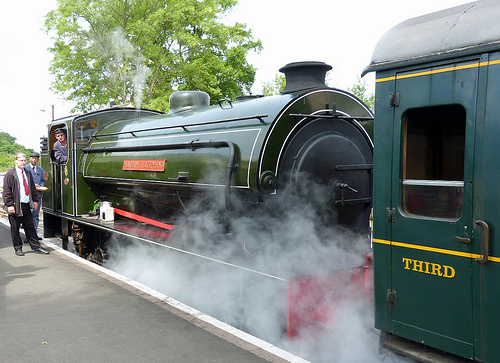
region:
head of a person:
[10, 150, 30, 165]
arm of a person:
[28, 179, 43, 200]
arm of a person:
[0, 175, 20, 207]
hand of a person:
[0, 208, 20, 214]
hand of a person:
[28, 195, 43, 213]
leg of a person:
[3, 213, 27, 248]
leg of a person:
[15, 210, 46, 242]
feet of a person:
[28, 242, 45, 253]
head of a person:
[53, 125, 73, 145]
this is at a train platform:
[18, 22, 476, 333]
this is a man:
[2, 155, 44, 250]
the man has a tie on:
[2, 145, 42, 257]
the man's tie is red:
[1, 167, 38, 197]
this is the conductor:
[42, 114, 94, 206]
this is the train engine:
[84, 89, 344, 361]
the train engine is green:
[162, 60, 387, 327]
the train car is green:
[394, 65, 498, 304]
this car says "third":
[392, 243, 482, 288]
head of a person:
[8, 146, 26, 173]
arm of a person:
[28, 173, 43, 203]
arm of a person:
[0, 173, 22, 213]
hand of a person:
[29, 197, 39, 209]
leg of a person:
[5, 202, 24, 239]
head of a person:
[23, 148, 50, 166]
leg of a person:
[22, 206, 46, 239]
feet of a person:
[3, 246, 25, 258]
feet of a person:
[29, 246, 56, 258]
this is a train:
[12, 100, 427, 350]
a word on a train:
[388, 249, 481, 299]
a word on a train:
[110, 150, 172, 174]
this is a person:
[2, 148, 50, 262]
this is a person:
[13, 140, 59, 236]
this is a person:
[32, 125, 94, 179]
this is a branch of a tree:
[33, 58, 126, 115]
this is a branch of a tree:
[42, 36, 119, 82]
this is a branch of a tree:
[169, 40, 249, 109]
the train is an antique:
[28, 63, 375, 320]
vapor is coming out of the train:
[106, 199, 391, 361]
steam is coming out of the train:
[106, 196, 374, 361]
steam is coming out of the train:
[111, 199, 376, 358]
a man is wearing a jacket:
[3, 168, 39, 216]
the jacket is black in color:
[6, 166, 38, 210]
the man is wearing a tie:
[18, 171, 30, 193]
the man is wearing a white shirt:
[17, 166, 29, 203]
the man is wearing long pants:
[6, 200, 41, 244]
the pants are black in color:
[6, 201, 41, 241]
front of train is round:
[253, 65, 366, 240]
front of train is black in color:
[274, 48, 379, 274]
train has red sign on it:
[103, 133, 210, 188]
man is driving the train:
[41, 118, 76, 163]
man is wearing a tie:
[17, 168, 33, 205]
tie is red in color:
[11, 158, 36, 203]